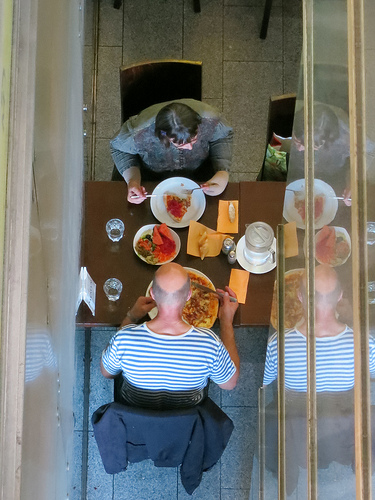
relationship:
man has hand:
[100, 259, 241, 409] [127, 295, 152, 316]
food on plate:
[164, 193, 192, 220] [148, 175, 206, 228]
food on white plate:
[179, 269, 218, 333] [143, 264, 219, 334]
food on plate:
[136, 222, 178, 264] [134, 222, 180, 264]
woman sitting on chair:
[110, 98, 232, 206] [110, 58, 203, 178]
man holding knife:
[100, 259, 241, 409] [194, 281, 225, 301]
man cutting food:
[100, 259, 241, 409] [149, 268, 219, 329]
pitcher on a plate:
[241, 216, 282, 273] [230, 217, 285, 276]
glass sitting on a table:
[105, 219, 124, 245] [74, 180, 372, 321]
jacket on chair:
[91, 395, 237, 498] [106, 56, 208, 184]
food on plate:
[141, 214, 191, 254] [155, 181, 212, 220]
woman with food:
[110, 98, 232, 206] [164, 191, 194, 223]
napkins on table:
[194, 213, 286, 315] [73, 165, 370, 330]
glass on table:
[105, 219, 124, 245] [80, 180, 288, 325]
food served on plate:
[164, 191, 194, 223] [146, 173, 208, 230]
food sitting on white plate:
[136, 222, 176, 261] [131, 224, 180, 263]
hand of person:
[202, 171, 232, 198] [107, 94, 236, 205]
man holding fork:
[100, 259, 241, 409] [179, 184, 213, 196]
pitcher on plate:
[243, 219, 277, 265] [235, 234, 276, 273]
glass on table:
[105, 219, 124, 245] [57, 169, 366, 336]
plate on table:
[144, 180, 210, 226] [80, 180, 288, 325]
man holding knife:
[100, 259, 241, 409] [192, 281, 221, 296]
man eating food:
[100, 259, 241, 409] [142, 273, 218, 319]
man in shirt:
[91, 245, 262, 431] [95, 314, 242, 390]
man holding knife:
[100, 259, 241, 409] [191, 279, 236, 300]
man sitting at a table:
[100, 259, 241, 409] [80, 180, 288, 325]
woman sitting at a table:
[110, 98, 235, 206] [80, 180, 288, 325]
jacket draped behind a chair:
[95, 383, 219, 478] [109, 363, 218, 474]